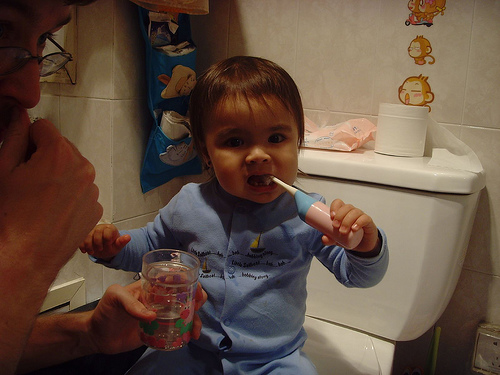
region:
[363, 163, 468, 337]
white toilet n bath room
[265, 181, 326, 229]
toothbrush held by baby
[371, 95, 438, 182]
white toilet tissue on toilet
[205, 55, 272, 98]
short brown hair on baby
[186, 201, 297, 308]
light blue shirt on baby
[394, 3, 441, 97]
cartoon decals on wall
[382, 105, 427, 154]
roll of toilet paper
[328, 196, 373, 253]
child's hand holding toothbrush handle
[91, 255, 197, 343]
woman's hand holding cup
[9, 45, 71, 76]
glasses on woman's face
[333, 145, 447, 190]
lid on the toilet tank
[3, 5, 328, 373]
woman and child in bathroom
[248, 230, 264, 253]
boat on child's shirt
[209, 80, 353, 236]
a child hodling toothbrush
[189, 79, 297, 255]
a child sitting on toilet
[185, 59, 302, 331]
a child wearing pjs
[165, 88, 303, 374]
a child wearin gblue pjs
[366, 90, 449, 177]
a roll of toilet paper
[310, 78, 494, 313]
a toilet in bathroom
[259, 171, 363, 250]
pink and blue child's toothbrush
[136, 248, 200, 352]
clear cup with a pig on it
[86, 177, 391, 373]
long sleeved blue onesie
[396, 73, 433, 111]
cartoon monkey sticker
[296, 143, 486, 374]
white ceramic toilet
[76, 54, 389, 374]
baby girl brushing her teeth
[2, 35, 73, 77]
black wire frame glasses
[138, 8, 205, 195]
blue hanging storage organizer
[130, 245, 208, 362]
clear glass in man's hand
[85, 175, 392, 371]
blue baby outfit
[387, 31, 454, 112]
yellow monkeys drawn on bathroom walls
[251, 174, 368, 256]
handle of electric toothbrush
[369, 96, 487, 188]
roll of white toilet tissue on top of white toilet tank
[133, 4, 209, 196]
blue pocket holder on wall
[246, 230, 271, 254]
image of sailboat on baby outfit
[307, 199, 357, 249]
the pink handle on brush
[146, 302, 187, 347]
water in the cup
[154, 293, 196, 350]
design on the cup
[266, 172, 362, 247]
the tooth brush is electric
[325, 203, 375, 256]
hand of a kid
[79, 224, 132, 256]
hand of a kid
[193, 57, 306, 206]
head of a kid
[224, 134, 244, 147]
eye of a kid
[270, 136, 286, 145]
eye of a kid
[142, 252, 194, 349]
a cup of water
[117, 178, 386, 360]
the shirt is blue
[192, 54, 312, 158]
the hair is brown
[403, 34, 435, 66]
monkey on the wall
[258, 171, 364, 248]
toothbrush in mouth of baby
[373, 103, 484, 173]
roll of white toilet paper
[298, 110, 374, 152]
bag of wipes osn toilet lid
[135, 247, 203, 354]
person holding colorful glass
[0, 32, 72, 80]
person wearing rimmed glasses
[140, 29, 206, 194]
blue organizer hanging on wall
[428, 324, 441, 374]
toilet brush handle is beige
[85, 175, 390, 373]
baby wearing light blue clothes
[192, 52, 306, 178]
baby has brown hair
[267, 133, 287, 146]
left eye of baby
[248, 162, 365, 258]
a pink and blue toothbrush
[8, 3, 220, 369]
man holding a glass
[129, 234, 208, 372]
water in the glass